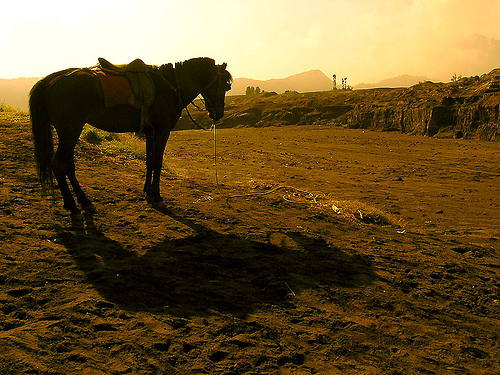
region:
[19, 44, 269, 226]
A brown horse in a field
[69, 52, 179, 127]
Saddle sitting on a horse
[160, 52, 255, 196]
Harness on a horse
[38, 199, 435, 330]
The shadow of a standing horse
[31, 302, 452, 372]
Dirt ground in the field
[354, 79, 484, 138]
Rocky edge in the field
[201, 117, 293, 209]
Rope hanging from a horses harness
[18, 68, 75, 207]
Long tail of a brown horse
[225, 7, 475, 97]
Mountains in the far distance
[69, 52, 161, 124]
Orange blanket under the horses saddle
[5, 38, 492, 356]
Harsh, desert-like landscape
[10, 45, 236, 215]
Silhouetted horse with saddle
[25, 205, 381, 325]
Dark, distinct shadow of horse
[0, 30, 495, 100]
Faded mountains in distance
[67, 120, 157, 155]
Sparse scrub brush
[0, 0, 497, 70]
Cloudy or hazy sky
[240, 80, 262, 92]
Tree-like growths in the distance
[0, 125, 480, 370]
Sand or harsh dirt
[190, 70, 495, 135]
Rocky landscape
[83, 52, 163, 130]
Sunlight highlighting top of horse's saddle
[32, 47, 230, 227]
horse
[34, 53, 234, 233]
horse pictured at sunset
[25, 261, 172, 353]
short green and brown grass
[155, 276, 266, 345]
short green and brown grass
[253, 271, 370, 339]
short green and brown grass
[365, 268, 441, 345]
short green and brown grass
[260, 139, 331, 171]
short green and brown grass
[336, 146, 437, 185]
short green and brown grass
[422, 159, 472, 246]
short green and brown grass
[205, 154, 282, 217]
short green and brown grass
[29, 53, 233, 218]
A horse standing in a field.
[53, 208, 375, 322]
Dark shadow of a horse on the ground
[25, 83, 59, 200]
Long dark hair of a horse tail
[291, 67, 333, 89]
Tallest peak in the distance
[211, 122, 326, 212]
Long rope coming off the front of a horse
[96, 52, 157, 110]
Small saddle on a horse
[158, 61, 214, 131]
Reins on a horse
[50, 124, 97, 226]
Two back legs on a horse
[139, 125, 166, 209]
Two front legs on a horse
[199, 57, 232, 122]
Head of a horse.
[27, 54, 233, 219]
a horse with saddle and reins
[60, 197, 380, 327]
the shadow of a horse on dirt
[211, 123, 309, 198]
a rope from a horse lying in dirt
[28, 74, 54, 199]
a horse's tail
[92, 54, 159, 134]
a saddle on a horse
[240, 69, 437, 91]
mountains on the horizon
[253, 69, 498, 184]
rock and dirt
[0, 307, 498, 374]
loose dirt with footprints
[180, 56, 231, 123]
head of a horse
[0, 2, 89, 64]
light from the sun